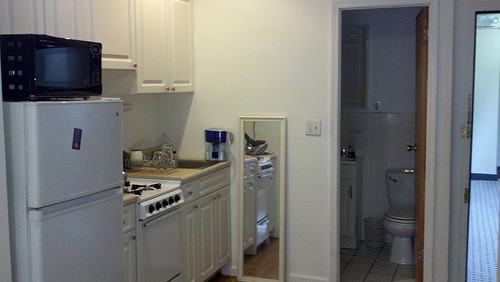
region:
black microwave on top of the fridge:
[1, 35, 104, 96]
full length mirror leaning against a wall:
[234, 115, 284, 280]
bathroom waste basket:
[360, 215, 384, 247]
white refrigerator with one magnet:
[12, 100, 124, 277]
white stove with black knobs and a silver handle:
[135, 181, 183, 279]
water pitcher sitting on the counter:
[203, 127, 235, 159]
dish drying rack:
[127, 145, 178, 173]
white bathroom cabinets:
[339, 160, 359, 247]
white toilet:
[383, 165, 415, 260]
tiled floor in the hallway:
[476, 182, 496, 277]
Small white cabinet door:
[168, 8, 197, 100]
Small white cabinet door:
[135, 2, 163, 100]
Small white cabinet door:
[90, 3, 136, 78]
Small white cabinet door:
[45, 1, 77, 36]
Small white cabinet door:
[7, 4, 71, 44]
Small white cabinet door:
[207, 194, 253, 262]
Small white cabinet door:
[183, 207, 217, 280]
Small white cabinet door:
[121, 234, 139, 280]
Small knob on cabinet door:
[186, 200, 203, 214]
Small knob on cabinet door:
[207, 186, 240, 208]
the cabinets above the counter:
[136, 3, 200, 94]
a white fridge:
[1, 103, 135, 270]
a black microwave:
[8, 35, 101, 90]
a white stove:
[131, 179, 189, 273]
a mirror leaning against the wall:
[240, 120, 281, 275]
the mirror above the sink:
[341, 30, 362, 97]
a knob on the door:
[406, 141, 416, 149]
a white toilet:
[382, 163, 416, 263]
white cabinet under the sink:
[343, 164, 358, 239]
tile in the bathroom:
[341, 248, 410, 279]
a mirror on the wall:
[241, 118, 282, 278]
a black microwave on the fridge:
[5, 35, 105, 91]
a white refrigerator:
[14, 102, 134, 280]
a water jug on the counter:
[203, 128, 233, 158]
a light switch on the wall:
[308, 120, 319, 131]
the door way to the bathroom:
[338, 10, 422, 279]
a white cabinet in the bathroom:
[339, 153, 359, 250]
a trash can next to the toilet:
[363, 215, 380, 244]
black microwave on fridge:
[5, 20, 134, 113]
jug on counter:
[188, 116, 240, 188]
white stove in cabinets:
[131, 170, 208, 280]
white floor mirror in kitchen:
[226, 95, 315, 280]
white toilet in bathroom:
[371, 138, 431, 280]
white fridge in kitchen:
[6, 96, 151, 280]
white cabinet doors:
[176, 132, 248, 278]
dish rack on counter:
[126, 134, 186, 185]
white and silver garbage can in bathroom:
[354, 204, 400, 272]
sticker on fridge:
[61, 116, 103, 177]